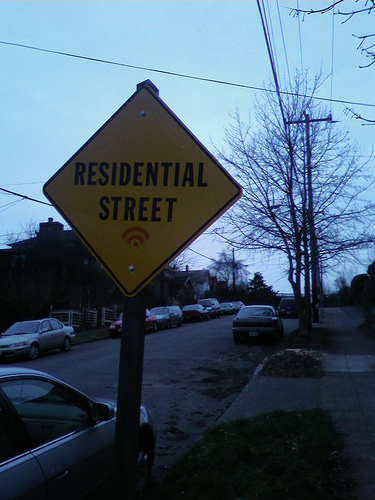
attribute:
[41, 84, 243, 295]
sign — yellow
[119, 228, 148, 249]
lines — orange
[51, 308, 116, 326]
fence — wood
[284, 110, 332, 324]
post — wooden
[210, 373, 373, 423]
drive way — concrete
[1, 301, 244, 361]
cars — parked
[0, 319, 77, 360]
car — light, sedan, silver, white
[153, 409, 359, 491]
grass — green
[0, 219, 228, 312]
houses — row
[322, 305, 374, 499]
sidewalk — cement, long, paved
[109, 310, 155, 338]
car — red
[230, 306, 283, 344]
car — black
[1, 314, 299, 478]
street — paved